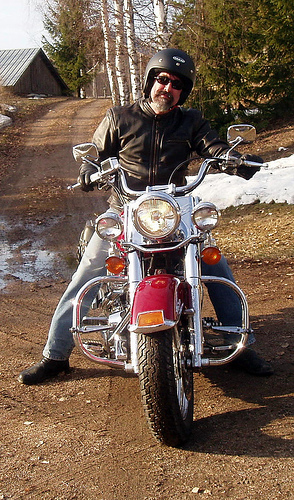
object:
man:
[19, 47, 273, 389]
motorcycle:
[68, 123, 267, 445]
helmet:
[142, 47, 195, 93]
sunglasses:
[155, 74, 184, 86]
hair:
[150, 87, 178, 116]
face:
[152, 71, 184, 112]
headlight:
[132, 194, 179, 239]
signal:
[198, 240, 220, 263]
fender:
[127, 273, 194, 333]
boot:
[16, 353, 71, 388]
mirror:
[224, 121, 257, 144]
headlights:
[190, 203, 218, 230]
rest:
[211, 320, 255, 335]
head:
[145, 49, 196, 111]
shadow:
[165, 299, 294, 460]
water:
[0, 232, 30, 279]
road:
[0, 82, 120, 319]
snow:
[261, 153, 292, 194]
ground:
[195, 125, 292, 267]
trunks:
[98, 0, 116, 109]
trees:
[44, 0, 108, 97]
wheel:
[135, 277, 192, 442]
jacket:
[81, 99, 242, 209]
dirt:
[2, 417, 73, 499]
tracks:
[2, 276, 116, 440]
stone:
[191, 484, 198, 492]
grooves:
[135, 335, 174, 444]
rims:
[174, 330, 197, 414]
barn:
[2, 45, 73, 96]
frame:
[65, 125, 267, 371]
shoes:
[19, 353, 68, 382]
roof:
[2, 47, 72, 88]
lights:
[104, 249, 126, 274]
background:
[1, 0, 286, 127]